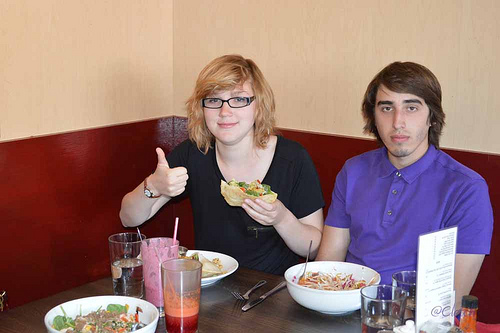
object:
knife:
[240, 282, 286, 311]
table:
[0, 265, 365, 333]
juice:
[163, 310, 199, 333]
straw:
[173, 217, 180, 245]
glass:
[160, 257, 203, 332]